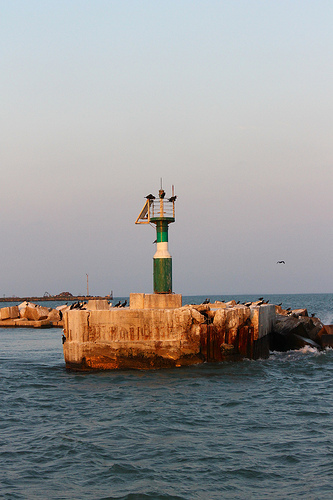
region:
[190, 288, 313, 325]
many birds rest on the large rocks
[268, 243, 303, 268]
one bird flies over the water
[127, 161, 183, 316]
a green and white structure sits on top of a rectangular base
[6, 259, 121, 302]
a long, commercial ship passes in back of the rocks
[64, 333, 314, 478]
the water is choppy as it flows past the rocks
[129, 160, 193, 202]
the structure has instruments with antennae on the top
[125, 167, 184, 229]
the railing at top supports a slanted metal structure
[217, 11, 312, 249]
the sky is different hues of grayish blue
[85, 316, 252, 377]
the rocks are worn and discolored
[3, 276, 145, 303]
a flat ship is at the horizon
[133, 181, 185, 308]
light buoy on a rock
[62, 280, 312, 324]
birds sitting on the rock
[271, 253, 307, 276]
bird flying in the air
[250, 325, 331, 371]
water splashing against the rocks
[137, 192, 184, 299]
the buoy is painted green and white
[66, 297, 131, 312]
the birds on the rocks are black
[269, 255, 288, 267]
a black bird is flying in the sky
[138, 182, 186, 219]
birds are sitting on top of the buoy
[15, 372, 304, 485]
the water is choppy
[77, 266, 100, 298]
a crane is standing behind the buoy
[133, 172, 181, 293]
A green and white observation tower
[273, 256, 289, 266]
A bird in flight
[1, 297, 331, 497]
A body of water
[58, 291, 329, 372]
A concrete island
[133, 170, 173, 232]
Birds perched on the top of an observation tower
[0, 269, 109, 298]
A barge floating in the distance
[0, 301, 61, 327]
Concrete fragments in the water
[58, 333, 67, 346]
A bird perched on the side of a concrete island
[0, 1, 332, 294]
A cloudy sky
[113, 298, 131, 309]
Two birds standing on a concrete island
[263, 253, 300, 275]
Bird flying in air above water.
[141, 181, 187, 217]
Three birds perched on top of structure.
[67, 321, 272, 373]
Water stains running across brown cement wall under structure.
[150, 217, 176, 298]
Green and white structure on top of brown cement wall.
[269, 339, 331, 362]
Crashing waves on right side of cement wall.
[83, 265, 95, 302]
Tall brown thin pole in background.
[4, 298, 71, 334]
Cement wall on left side of picture.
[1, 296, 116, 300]
Long dock in background of picture.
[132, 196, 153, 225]
Yellow triangle shape near the top of the green and white structure.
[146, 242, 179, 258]
White color on green pole on cement wall structure.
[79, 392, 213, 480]
choppy blue water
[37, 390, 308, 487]
lapping ocean waves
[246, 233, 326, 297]
a bird flies over the water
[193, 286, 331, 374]
birds perched on a rock in the water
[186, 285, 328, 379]
a rock juts from the water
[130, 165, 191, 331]
a green tower extends from the rock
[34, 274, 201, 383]
the bottom of the rock is wet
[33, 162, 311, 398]
grey sky over a bay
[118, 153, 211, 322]
a cement and metal structure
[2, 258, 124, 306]
a shipping dock